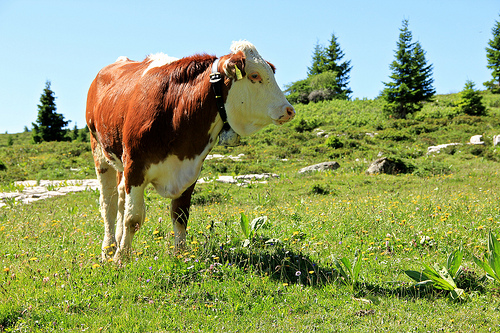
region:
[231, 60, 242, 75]
The yellow tag on the cow's ear.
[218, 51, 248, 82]
The left ear of the cow.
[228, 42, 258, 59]
The lump on the top of the cow's head.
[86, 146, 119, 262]
The back left leg of the cow.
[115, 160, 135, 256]
The front left leg of the cow.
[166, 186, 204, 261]
The front right leg of the cow.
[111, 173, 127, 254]
The back right leg of the cow.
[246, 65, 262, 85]
The eye of the cow.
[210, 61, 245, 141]
The collar and bell around the cow's neck.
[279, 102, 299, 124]
The nose of the cow.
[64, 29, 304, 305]
cow in a field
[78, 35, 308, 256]
cow on the grass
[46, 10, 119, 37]
the clear blue sky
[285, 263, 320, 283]
dandelions in the grass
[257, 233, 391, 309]
the shadow on the grass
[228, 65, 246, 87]
the cow is tagged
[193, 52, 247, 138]
the collar on the cow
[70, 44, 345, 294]
the cow is brown and white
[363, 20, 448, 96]
the pine tree on the hill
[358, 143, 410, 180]
a large stone in the field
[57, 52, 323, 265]
A cow alone in a pasture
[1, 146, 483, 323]
The pasture is green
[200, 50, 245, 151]
Bell around the cow's neck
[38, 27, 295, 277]
The cow is brown and white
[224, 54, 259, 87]
A yellow tag on the cow's ear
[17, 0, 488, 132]
The sky is clear and blue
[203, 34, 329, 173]
The cow is looking to the left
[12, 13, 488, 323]
Photo taken during the day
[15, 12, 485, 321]
The season is summer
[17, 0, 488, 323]
Nobody in the photo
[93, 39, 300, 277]
large brown and white cow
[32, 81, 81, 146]
small but sturdy evergreen tree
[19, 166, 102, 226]
paved gravel area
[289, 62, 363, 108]
collection of small green shrubbery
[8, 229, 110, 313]
floor of yellow dandelions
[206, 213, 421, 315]
collections of grass and weeds for the cow to forage on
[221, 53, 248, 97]
Yellow ear tag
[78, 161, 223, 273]
gorgeous white markings on underbelly and legs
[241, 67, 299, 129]
beautiful brown eyes and sullen face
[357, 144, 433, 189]
small boulders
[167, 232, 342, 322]
flowers in the grass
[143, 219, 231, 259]
yellow flowers in grass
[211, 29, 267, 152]
tag is on cow ear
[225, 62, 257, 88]
the tag is yellow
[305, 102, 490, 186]
rocks on the hill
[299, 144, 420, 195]
the rocks are gray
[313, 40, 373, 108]
trees on the hill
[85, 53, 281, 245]
the cow is standing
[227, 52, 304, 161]
the cow has white face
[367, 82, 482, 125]
shrubs on the hill